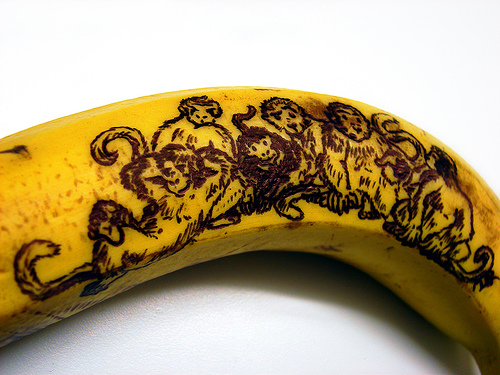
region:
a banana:
[79, 105, 286, 279]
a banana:
[66, 139, 151, 210]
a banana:
[114, 150, 291, 360]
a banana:
[76, 114, 204, 252]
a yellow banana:
[0, 83, 499, 374]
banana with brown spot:
[1, 137, 33, 166]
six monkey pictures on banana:
[14, 96, 494, 302]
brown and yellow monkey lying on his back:
[11, 142, 237, 299]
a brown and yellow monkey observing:
[89, 96, 238, 167]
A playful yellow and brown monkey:
[232, 102, 306, 215]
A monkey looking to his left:
[391, 141, 496, 284]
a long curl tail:
[12, 237, 95, 303]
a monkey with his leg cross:
[81, 199, 149, 297]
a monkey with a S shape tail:
[371, 110, 428, 170]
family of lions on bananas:
[8, 90, 494, 295]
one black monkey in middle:
[228, 108, 298, 208]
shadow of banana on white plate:
[116, 212, 476, 366]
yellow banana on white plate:
[0, 0, 497, 371]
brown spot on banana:
[0, 135, 40, 170]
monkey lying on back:
[70, 140, 235, 266]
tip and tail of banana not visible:
[1, 83, 498, 372]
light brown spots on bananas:
[0, 159, 498, 268]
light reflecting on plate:
[1, 2, 499, 371]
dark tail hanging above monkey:
[226, 98, 262, 138]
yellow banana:
[2, 77, 498, 367]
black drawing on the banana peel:
[11, 86, 498, 324]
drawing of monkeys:
[11, 97, 499, 322]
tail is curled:
[75, 112, 154, 171]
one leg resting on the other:
[78, 191, 163, 293]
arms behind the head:
[107, 136, 248, 204]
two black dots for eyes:
[243, 135, 271, 154]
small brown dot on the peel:
[68, 176, 88, 190]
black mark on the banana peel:
[3, 140, 43, 160]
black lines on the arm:
[323, 157, 350, 187]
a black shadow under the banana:
[110, 242, 472, 373]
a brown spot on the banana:
[46, 200, 62, 222]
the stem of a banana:
[476, 334, 498, 373]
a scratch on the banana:
[1, 137, 38, 162]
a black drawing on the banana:
[11, 85, 499, 315]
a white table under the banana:
[0, 0, 499, 374]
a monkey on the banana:
[8, 139, 235, 308]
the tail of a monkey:
[13, 234, 97, 305]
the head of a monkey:
[153, 136, 204, 200]